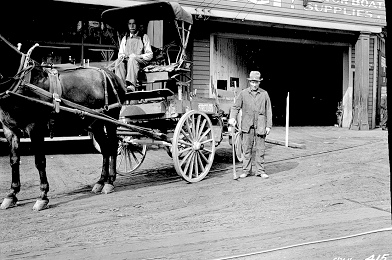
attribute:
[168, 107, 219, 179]
wheel — wooden 